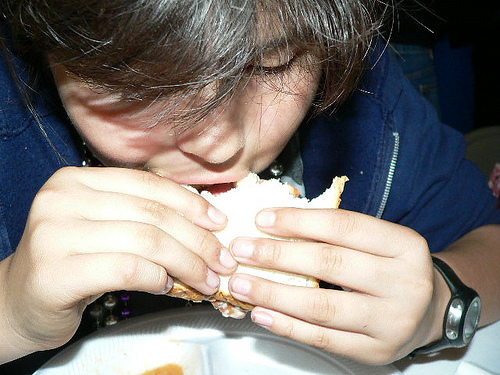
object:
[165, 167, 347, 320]
bread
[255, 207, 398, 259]
fingers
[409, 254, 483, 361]
watch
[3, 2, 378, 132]
hair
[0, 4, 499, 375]
person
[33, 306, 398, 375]
plate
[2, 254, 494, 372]
table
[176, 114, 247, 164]
nose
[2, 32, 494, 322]
sweater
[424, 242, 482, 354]
wrist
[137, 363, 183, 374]
stain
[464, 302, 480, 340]
face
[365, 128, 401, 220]
zipper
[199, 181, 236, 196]
mouth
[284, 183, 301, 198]
meat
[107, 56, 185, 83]
eyes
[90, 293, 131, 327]
beads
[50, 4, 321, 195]
face